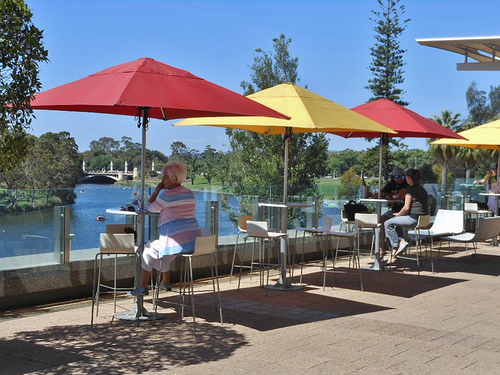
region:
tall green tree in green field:
[357, 1, 417, 168]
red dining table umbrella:
[4, 41, 291, 216]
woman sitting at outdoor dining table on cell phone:
[13, 50, 292, 339]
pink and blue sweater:
[145, 180, 205, 257]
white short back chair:
[235, 212, 290, 302]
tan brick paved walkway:
[5, 209, 499, 371]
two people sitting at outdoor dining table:
[340, 144, 443, 289]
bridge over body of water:
[72, 155, 141, 185]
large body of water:
[2, 168, 367, 260]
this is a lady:
[129, 163, 216, 297]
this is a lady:
[376, 172, 443, 264]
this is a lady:
[370, 148, 424, 247]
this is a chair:
[80, 208, 147, 320]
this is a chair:
[175, 223, 226, 327]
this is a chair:
[229, 208, 292, 270]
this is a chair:
[314, 220, 377, 294]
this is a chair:
[406, 210, 439, 280]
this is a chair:
[437, 205, 495, 259]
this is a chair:
[391, 199, 450, 270]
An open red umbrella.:
[8, 58, 290, 121]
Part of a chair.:
[196, 236, 217, 251]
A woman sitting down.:
[127, 162, 203, 297]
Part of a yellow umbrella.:
[294, 100, 323, 117]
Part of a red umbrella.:
[386, 99, 393, 124]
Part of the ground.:
[352, 338, 396, 371]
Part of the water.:
[99, 191, 111, 206]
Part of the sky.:
[82, 119, 103, 139]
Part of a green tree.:
[38, 148, 63, 173]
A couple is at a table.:
[381, 161, 431, 268]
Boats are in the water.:
[88, 209, 108, 224]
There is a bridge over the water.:
[73, 154, 160, 185]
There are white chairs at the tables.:
[319, 218, 364, 293]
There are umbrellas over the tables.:
[169, 81, 402, 137]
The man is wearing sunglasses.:
[391, 170, 408, 180]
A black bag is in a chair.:
[340, 198, 369, 223]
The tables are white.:
[256, 197, 313, 211]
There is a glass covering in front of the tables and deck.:
[2, 183, 95, 257]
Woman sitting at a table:
[143, 171, 206, 306]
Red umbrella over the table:
[3, 46, 294, 148]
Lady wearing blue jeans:
[382, 167, 432, 251]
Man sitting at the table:
[379, 164, 416, 249]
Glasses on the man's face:
[389, 171, 409, 183]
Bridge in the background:
[69, 150, 160, 185]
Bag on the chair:
[341, 192, 372, 224]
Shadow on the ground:
[142, 278, 392, 349]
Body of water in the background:
[1, 171, 376, 256]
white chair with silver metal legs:
[90, 231, 142, 325]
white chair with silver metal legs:
[181, 234, 226, 324]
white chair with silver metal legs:
[244, 216, 284, 293]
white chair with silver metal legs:
[227, 212, 260, 282]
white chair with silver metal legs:
[295, 216, 331, 281]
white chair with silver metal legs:
[326, 223, 360, 292]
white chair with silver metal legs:
[405, 214, 432, 272]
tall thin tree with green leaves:
[363, 1, 408, 190]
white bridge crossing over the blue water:
[77, 159, 142, 186]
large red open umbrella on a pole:
[334, 97, 469, 142]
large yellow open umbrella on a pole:
[173, 83, 395, 135]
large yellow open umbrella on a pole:
[430, 113, 498, 153]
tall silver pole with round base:
[120, 122, 147, 320]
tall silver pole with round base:
[265, 134, 302, 294]